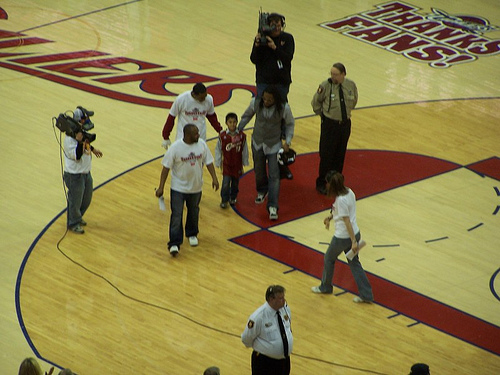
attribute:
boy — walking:
[212, 113, 251, 210]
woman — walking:
[310, 168, 377, 305]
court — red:
[6, 4, 496, 367]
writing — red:
[316, 0, 499, 72]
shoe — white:
[169, 244, 182, 257]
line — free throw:
[289, 182, 452, 216]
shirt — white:
[330, 188, 363, 240]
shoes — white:
[160, 233, 200, 256]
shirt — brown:
[310, 78, 359, 122]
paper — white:
[153, 185, 167, 212]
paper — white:
[343, 241, 368, 263]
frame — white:
[344, 31, 364, 39]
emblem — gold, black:
[316, 84, 327, 97]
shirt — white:
[159, 92, 224, 146]